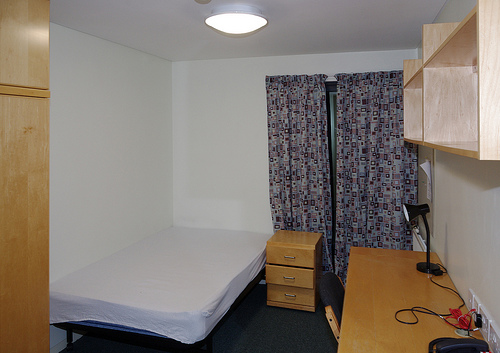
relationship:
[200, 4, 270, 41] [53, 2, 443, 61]
light on ceiling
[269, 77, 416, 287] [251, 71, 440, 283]
curtains covering window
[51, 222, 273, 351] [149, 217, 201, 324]
bed covered with sheet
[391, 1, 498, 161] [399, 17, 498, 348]
shelving on wall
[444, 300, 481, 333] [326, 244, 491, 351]
cord on desk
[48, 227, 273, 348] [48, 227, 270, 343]
mattress with sheet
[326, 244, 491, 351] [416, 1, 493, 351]
desk against wall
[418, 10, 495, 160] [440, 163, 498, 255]
shelf attached to wall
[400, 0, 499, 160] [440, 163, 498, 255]
shelf attached to wall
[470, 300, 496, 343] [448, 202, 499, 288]
outlets in wall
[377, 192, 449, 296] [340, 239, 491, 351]
lamp on table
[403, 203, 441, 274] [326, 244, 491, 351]
lamp on a desk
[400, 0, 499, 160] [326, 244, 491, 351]
shelf above a desk